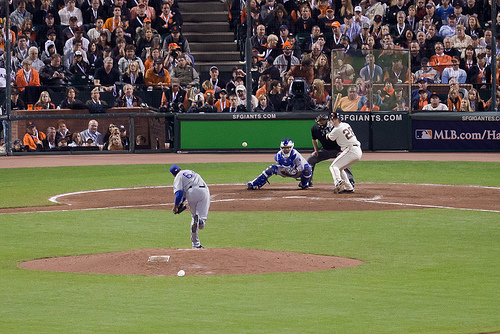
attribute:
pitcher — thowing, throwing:
[170, 164, 211, 249]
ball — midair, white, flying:
[240, 141, 248, 148]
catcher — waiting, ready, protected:
[245, 137, 314, 194]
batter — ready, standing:
[325, 110, 365, 195]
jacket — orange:
[15, 67, 43, 89]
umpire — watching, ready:
[307, 113, 356, 193]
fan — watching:
[40, 39, 60, 64]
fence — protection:
[329, 47, 413, 113]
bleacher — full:
[2, 2, 190, 116]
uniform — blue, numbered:
[170, 169, 211, 244]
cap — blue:
[171, 162, 182, 175]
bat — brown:
[329, 91, 344, 123]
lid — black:
[330, 111, 340, 119]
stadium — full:
[1, 1, 499, 112]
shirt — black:
[311, 125, 342, 152]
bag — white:
[175, 269, 190, 278]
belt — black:
[343, 143, 363, 148]